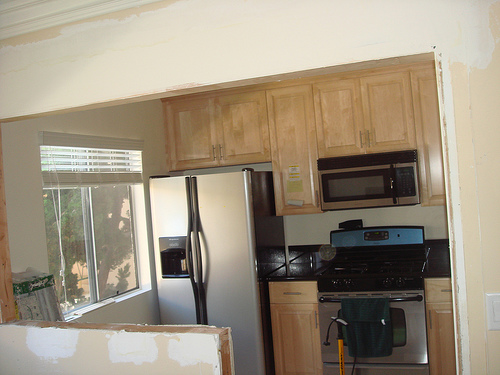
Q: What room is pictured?
A: It is a kitchen.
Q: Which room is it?
A: It is a kitchen.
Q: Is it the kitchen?
A: Yes, it is the kitchen.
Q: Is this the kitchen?
A: Yes, it is the kitchen.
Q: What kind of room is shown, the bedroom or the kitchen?
A: It is the kitchen.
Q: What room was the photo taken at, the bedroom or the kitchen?
A: It was taken at the kitchen.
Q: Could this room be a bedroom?
A: No, it is a kitchen.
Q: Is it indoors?
A: Yes, it is indoors.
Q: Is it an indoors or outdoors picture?
A: It is indoors.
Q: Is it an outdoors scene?
A: No, it is indoors.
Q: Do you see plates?
A: Yes, there is a plate.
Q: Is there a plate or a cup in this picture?
A: Yes, there is a plate.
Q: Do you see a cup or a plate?
A: Yes, there is a plate.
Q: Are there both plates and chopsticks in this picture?
A: No, there is a plate but no chopsticks.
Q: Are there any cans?
A: No, there are no cans.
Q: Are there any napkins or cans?
A: No, there are no cans or napkins.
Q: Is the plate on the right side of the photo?
A: Yes, the plate is on the right of the image.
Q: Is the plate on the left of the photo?
A: No, the plate is on the right of the image.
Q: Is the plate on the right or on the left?
A: The plate is on the right of the image.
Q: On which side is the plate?
A: The plate is on the right of the image.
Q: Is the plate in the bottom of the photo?
A: Yes, the plate is in the bottom of the image.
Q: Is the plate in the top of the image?
A: No, the plate is in the bottom of the image.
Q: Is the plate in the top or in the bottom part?
A: The plate is in the bottom of the image.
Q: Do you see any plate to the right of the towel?
A: Yes, there is a plate to the right of the towel.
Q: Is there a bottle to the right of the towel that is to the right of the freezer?
A: No, there is a plate to the right of the towel.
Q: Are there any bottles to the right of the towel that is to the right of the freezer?
A: No, there is a plate to the right of the towel.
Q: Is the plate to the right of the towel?
A: Yes, the plate is to the right of the towel.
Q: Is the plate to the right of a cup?
A: No, the plate is to the right of the towel.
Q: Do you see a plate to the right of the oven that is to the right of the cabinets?
A: Yes, there is a plate to the right of the oven.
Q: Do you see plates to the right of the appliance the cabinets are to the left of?
A: Yes, there is a plate to the right of the oven.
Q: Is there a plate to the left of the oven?
A: No, the plate is to the right of the oven.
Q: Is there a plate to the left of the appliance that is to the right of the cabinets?
A: No, the plate is to the right of the oven.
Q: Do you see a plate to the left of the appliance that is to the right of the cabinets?
A: No, the plate is to the right of the oven.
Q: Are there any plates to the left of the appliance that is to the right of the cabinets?
A: No, the plate is to the right of the oven.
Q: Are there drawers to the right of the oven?
A: No, there is a plate to the right of the oven.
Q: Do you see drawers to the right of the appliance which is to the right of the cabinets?
A: No, there is a plate to the right of the oven.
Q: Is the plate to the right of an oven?
A: Yes, the plate is to the right of an oven.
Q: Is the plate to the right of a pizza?
A: No, the plate is to the right of an oven.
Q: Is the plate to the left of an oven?
A: No, the plate is to the right of an oven.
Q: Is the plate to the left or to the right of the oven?
A: The plate is to the right of the oven.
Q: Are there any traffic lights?
A: No, there are no traffic lights.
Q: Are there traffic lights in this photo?
A: No, there are no traffic lights.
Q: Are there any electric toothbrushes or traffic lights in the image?
A: No, there are no traffic lights or electric toothbrushes.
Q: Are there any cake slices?
A: No, there are no cake slices.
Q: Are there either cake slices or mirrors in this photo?
A: No, there are no cake slices or mirrors.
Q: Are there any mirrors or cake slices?
A: No, there are no cake slices or mirrors.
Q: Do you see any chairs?
A: No, there are no chairs.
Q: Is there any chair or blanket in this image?
A: No, there are no chairs or blankets.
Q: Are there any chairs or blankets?
A: No, there are no chairs or blankets.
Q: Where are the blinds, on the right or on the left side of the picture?
A: The blinds are on the left of the image.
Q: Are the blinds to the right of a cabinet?
A: No, the blinds are to the left of a cabinet.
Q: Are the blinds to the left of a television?
A: No, the blinds are to the left of a cabinet.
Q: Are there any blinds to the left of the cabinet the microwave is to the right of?
A: Yes, there are blinds to the left of the cabinet.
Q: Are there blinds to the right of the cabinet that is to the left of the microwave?
A: No, the blinds are to the left of the cabinet.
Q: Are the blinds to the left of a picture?
A: No, the blinds are to the left of the cabinet.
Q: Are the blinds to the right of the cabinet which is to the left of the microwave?
A: No, the blinds are to the left of the cabinet.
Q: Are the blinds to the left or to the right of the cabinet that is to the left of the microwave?
A: The blinds are to the left of the cabinet.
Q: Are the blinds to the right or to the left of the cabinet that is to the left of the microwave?
A: The blinds are to the left of the cabinet.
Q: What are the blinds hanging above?
A: The blinds are hanging above the window.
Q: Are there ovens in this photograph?
A: Yes, there is an oven.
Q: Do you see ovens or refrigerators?
A: Yes, there is an oven.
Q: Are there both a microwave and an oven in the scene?
A: Yes, there are both an oven and a microwave.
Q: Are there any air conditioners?
A: No, there are no air conditioners.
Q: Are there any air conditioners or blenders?
A: No, there are no air conditioners or blenders.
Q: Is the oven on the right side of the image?
A: Yes, the oven is on the right of the image.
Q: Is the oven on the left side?
A: No, the oven is on the right of the image.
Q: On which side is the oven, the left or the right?
A: The oven is on the right of the image.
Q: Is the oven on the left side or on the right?
A: The oven is on the right of the image.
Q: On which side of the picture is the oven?
A: The oven is on the right of the image.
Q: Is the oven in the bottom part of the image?
A: Yes, the oven is in the bottom of the image.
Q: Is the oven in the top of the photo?
A: No, the oven is in the bottom of the image.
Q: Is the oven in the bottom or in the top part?
A: The oven is in the bottom of the image.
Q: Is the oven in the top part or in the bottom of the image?
A: The oven is in the bottom of the image.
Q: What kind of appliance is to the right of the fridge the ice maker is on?
A: The appliance is an oven.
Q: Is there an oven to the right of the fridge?
A: Yes, there is an oven to the right of the fridge.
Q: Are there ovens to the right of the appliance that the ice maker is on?
A: Yes, there is an oven to the right of the fridge.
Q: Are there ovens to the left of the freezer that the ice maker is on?
A: No, the oven is to the right of the refrigerator.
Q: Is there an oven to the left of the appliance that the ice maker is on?
A: No, the oven is to the right of the refrigerator.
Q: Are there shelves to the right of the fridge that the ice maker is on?
A: No, there is an oven to the right of the refrigerator.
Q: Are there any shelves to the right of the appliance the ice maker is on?
A: No, there is an oven to the right of the refrigerator.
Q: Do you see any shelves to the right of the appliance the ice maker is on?
A: No, there is an oven to the right of the refrigerator.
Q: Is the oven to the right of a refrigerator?
A: Yes, the oven is to the right of a refrigerator.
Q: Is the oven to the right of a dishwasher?
A: No, the oven is to the right of a refrigerator.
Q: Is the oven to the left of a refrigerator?
A: No, the oven is to the right of a refrigerator.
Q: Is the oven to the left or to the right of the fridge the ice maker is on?
A: The oven is to the right of the refrigerator.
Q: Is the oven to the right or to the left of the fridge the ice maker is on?
A: The oven is to the right of the refrigerator.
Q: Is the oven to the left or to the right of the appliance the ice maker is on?
A: The oven is to the right of the refrigerator.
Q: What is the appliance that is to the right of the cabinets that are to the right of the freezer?
A: The appliance is an oven.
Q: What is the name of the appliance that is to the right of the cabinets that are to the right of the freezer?
A: The appliance is an oven.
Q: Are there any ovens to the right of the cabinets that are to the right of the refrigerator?
A: Yes, there is an oven to the right of the cabinets.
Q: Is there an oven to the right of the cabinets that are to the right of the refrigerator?
A: Yes, there is an oven to the right of the cabinets.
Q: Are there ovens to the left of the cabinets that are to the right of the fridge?
A: No, the oven is to the right of the cabinets.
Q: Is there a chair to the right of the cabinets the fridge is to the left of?
A: No, there is an oven to the right of the cabinets.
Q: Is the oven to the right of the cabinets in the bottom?
A: Yes, the oven is to the right of the cabinets.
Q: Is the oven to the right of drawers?
A: No, the oven is to the right of the cabinets.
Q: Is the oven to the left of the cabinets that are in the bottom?
A: No, the oven is to the right of the cabinets.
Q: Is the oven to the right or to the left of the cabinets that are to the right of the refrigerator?
A: The oven is to the right of the cabinets.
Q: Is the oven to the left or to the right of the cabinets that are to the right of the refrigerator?
A: The oven is to the right of the cabinets.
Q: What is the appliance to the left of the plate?
A: The appliance is an oven.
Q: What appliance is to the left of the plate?
A: The appliance is an oven.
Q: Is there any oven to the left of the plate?
A: Yes, there is an oven to the left of the plate.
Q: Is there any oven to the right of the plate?
A: No, the oven is to the left of the plate.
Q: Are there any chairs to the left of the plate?
A: No, there is an oven to the left of the plate.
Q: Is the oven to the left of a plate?
A: Yes, the oven is to the left of a plate.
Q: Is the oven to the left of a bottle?
A: No, the oven is to the left of a plate.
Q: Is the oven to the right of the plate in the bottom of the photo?
A: No, the oven is to the left of the plate.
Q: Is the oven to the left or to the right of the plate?
A: The oven is to the left of the plate.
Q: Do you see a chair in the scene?
A: No, there are no chairs.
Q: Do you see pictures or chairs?
A: No, there are no chairs or pictures.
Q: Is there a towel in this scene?
A: Yes, there is a towel.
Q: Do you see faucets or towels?
A: Yes, there is a towel.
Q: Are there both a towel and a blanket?
A: No, there is a towel but no blankets.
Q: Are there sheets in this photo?
A: No, there are no sheets.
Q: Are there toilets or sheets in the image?
A: No, there are no sheets or toilets.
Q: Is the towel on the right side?
A: Yes, the towel is on the right of the image.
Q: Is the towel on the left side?
A: No, the towel is on the right of the image.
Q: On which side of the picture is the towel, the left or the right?
A: The towel is on the right of the image.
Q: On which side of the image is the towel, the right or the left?
A: The towel is on the right of the image.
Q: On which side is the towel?
A: The towel is on the right of the image.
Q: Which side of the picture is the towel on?
A: The towel is on the right of the image.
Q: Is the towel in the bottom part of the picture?
A: Yes, the towel is in the bottom of the image.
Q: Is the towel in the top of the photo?
A: No, the towel is in the bottom of the image.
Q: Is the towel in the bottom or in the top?
A: The towel is in the bottom of the image.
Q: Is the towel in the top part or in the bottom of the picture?
A: The towel is in the bottom of the image.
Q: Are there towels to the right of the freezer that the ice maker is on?
A: Yes, there is a towel to the right of the refrigerator.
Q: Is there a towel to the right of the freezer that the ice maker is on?
A: Yes, there is a towel to the right of the refrigerator.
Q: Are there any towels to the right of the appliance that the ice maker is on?
A: Yes, there is a towel to the right of the refrigerator.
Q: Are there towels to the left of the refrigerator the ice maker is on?
A: No, the towel is to the right of the fridge.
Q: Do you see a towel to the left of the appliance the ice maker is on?
A: No, the towel is to the right of the fridge.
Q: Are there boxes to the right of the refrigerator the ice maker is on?
A: No, there is a towel to the right of the refrigerator.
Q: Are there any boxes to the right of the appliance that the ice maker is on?
A: No, there is a towel to the right of the refrigerator.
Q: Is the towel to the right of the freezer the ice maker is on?
A: Yes, the towel is to the right of the freezer.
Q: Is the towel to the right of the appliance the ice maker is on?
A: Yes, the towel is to the right of the freezer.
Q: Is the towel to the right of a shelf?
A: No, the towel is to the right of the freezer.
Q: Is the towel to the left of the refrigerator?
A: No, the towel is to the right of the refrigerator.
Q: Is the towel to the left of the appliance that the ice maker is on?
A: No, the towel is to the right of the refrigerator.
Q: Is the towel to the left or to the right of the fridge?
A: The towel is to the right of the fridge.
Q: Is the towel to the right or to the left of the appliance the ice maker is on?
A: The towel is to the right of the fridge.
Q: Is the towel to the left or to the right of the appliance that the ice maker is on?
A: The towel is to the right of the fridge.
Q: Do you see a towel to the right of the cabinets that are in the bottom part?
A: Yes, there is a towel to the right of the cabinets.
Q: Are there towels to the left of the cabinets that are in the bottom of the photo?
A: No, the towel is to the right of the cabinets.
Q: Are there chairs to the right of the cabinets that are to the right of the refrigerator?
A: No, there is a towel to the right of the cabinets.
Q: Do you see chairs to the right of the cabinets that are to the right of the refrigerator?
A: No, there is a towel to the right of the cabinets.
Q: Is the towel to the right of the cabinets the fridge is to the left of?
A: Yes, the towel is to the right of the cabinets.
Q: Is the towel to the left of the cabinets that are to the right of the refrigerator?
A: No, the towel is to the right of the cabinets.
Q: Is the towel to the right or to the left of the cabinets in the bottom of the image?
A: The towel is to the right of the cabinets.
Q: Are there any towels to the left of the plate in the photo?
A: Yes, there is a towel to the left of the plate.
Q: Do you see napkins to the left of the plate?
A: No, there is a towel to the left of the plate.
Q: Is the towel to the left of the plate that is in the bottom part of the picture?
A: Yes, the towel is to the left of the plate.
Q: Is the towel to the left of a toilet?
A: No, the towel is to the left of the plate.